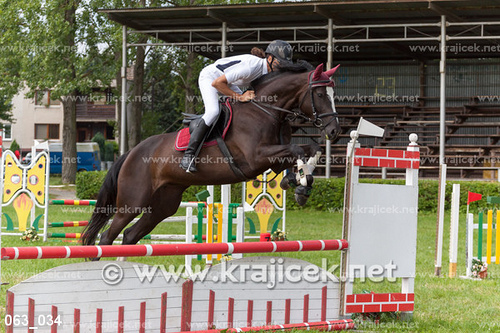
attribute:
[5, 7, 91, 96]
tree leaves — green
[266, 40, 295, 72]
helmet — black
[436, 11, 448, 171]
pole — tall, gray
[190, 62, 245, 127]
pants — white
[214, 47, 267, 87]
shirt — white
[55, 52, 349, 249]
horse — brown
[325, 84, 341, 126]
mark — white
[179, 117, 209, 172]
boot — black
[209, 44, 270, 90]
shirt — white, black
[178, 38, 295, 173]
jokey — small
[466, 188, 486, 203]
flag — red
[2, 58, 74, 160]
building — tan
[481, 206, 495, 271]
pole — tall, yellow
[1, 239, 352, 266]
pole — white, red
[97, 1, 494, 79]
roof — dark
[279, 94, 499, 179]
stands — wooden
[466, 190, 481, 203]
red flag — small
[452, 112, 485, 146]
section — small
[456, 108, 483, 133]
section — small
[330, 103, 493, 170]
bleachers — empty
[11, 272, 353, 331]
vertical lines — red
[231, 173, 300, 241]
butterfly support — yellow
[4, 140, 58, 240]
butterfly support — yellow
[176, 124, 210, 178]
boot — black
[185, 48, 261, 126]
outfit — white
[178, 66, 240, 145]
pants — white